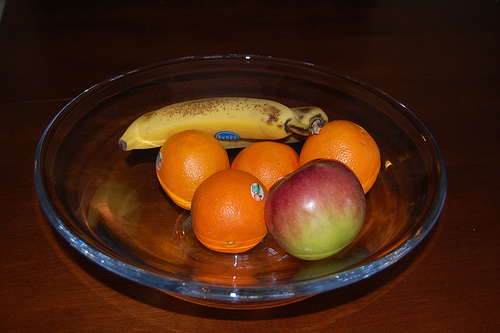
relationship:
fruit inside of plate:
[106, 89, 380, 255] [31, 38, 477, 308]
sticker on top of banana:
[213, 123, 246, 147] [96, 91, 340, 149]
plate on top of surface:
[31, 38, 477, 308] [5, 2, 493, 327]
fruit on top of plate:
[106, 89, 380, 255] [31, 38, 477, 308]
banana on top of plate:
[96, 91, 340, 149] [31, 38, 477, 308]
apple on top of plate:
[244, 153, 381, 265] [31, 38, 477, 308]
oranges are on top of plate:
[142, 120, 371, 246] [31, 38, 477, 308]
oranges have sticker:
[142, 120, 371, 246] [244, 178, 265, 202]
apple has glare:
[244, 153, 381, 265] [300, 196, 321, 216]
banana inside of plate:
[96, 91, 340, 149] [31, 38, 477, 308]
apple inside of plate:
[244, 153, 381, 265] [31, 38, 477, 308]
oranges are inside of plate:
[142, 120, 371, 246] [31, 38, 477, 308]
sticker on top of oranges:
[244, 178, 265, 202] [142, 120, 371, 246]